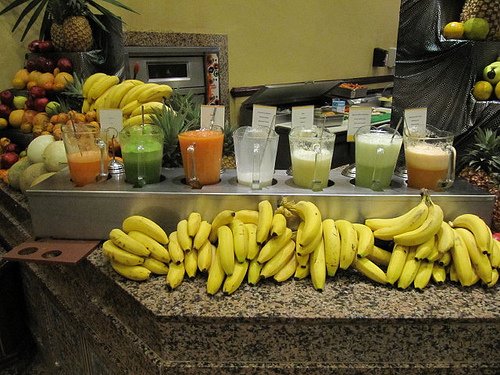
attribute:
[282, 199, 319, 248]
banana — yellow, stained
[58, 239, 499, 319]
counter — stone, marble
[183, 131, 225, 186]
liquid — orange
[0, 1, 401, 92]
wall — gold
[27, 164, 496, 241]
bin — silver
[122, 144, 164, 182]
juice — green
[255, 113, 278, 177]
stirrer — silver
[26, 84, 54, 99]
mango — ripe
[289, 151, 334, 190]
smoothy — fruit, green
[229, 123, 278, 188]
pitcher — empty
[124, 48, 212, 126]
oven — stainless